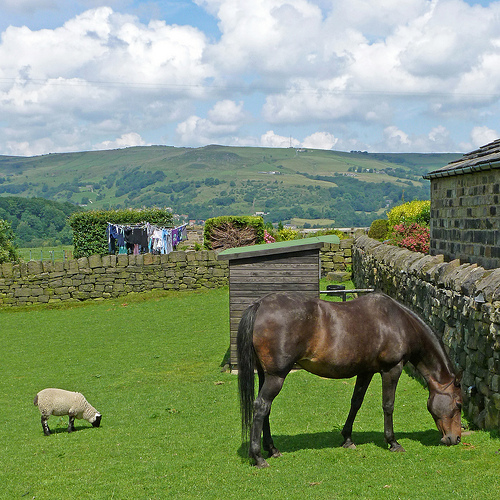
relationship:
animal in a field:
[33, 388, 101, 436] [60, 310, 195, 383]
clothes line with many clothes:
[101, 217, 196, 237] [104, 217, 189, 257]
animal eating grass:
[236, 288, 464, 466] [271, 403, 498, 497]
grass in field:
[271, 403, 498, 497] [6, 299, 498, 498]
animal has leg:
[236, 288, 464, 466] [239, 320, 314, 458]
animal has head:
[236, 288, 464, 466] [426, 383, 464, 446]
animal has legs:
[236, 288, 464, 466] [377, 365, 429, 466]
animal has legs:
[236, 288, 464, 466] [321, 355, 371, 467]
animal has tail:
[236, 288, 464, 466] [237, 301, 259, 463]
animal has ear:
[236, 288, 464, 466] [430, 365, 455, 400]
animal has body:
[236, 288, 464, 466] [299, 292, 369, 376]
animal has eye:
[236, 288, 464, 466] [456, 401, 466, 423]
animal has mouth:
[236, 288, 464, 466] [431, 427, 457, 448]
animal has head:
[33, 388, 101, 436] [88, 402, 104, 437]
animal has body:
[33, 388, 101, 436] [42, 387, 87, 420]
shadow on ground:
[249, 427, 451, 459] [66, 463, 465, 487]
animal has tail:
[236, 288, 464, 466] [234, 302, 255, 455]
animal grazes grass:
[33, 388, 101, 436] [0, 276, 498, 498]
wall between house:
[351, 232, 499, 427] [421, 137, 498, 267]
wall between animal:
[351, 232, 499, 427] [236, 288, 464, 466]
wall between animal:
[351, 232, 499, 427] [33, 389, 101, 433]